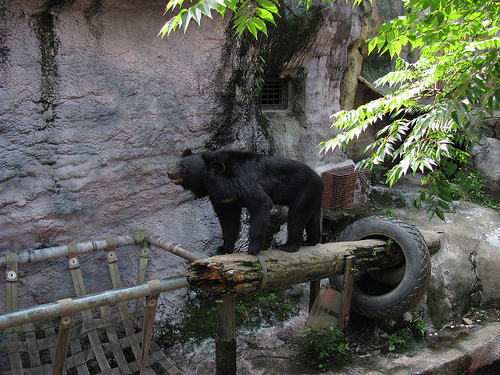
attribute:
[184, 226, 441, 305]
log — wooden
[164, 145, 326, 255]
bear — black, large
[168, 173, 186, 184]
mouth — open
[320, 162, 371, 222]
basket — metal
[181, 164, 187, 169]
eye — black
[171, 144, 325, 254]
fur — black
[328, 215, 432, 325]
tire — black, rubber, round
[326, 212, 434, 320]
tire — round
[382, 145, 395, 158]
tree leaf — sunlit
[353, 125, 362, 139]
tree leaf — sunlit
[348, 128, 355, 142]
tree leaf — sunlit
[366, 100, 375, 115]
tree leaf — sunlit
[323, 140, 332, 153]
tree leaf — sunlit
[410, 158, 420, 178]
leaf — green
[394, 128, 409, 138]
leaf — green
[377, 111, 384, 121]
leaf — green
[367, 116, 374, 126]
leaf — green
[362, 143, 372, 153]
leaf — green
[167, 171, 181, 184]
tongue — red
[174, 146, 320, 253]
bear — furry, black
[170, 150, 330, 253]
bear — black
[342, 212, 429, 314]
tire — black, old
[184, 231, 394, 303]
log — old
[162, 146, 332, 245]
bear — black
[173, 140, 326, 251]
bear — black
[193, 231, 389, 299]
log — large